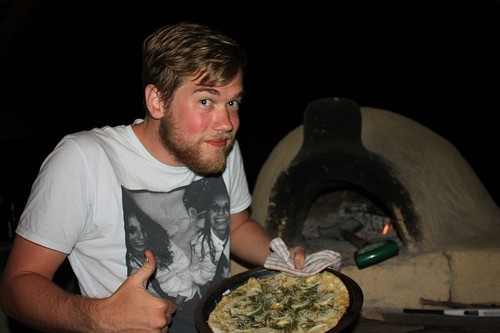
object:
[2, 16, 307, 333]
man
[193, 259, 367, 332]
plate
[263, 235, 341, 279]
rag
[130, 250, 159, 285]
thumb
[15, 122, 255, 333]
shirt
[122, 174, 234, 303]
photo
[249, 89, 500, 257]
oven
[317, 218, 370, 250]
shovel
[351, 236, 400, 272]
handle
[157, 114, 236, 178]
beard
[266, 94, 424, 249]
opening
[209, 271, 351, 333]
pizza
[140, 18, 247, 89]
hair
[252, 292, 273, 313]
toppings